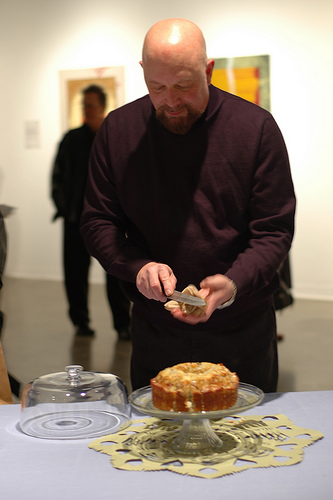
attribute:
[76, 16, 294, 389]
man — bald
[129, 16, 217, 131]
head — bald, cleanshaven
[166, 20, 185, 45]
spot — shiny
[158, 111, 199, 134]
beard — brown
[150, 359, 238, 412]
cake — present, frosted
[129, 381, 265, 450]
server — crystal, plate, clear, glass, platter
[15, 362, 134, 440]
lid — glass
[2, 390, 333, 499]
table — baby blue, purple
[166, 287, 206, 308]
knife — large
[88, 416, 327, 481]
placemat — large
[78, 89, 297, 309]
shirt — brown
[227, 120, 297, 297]
sleeve — long